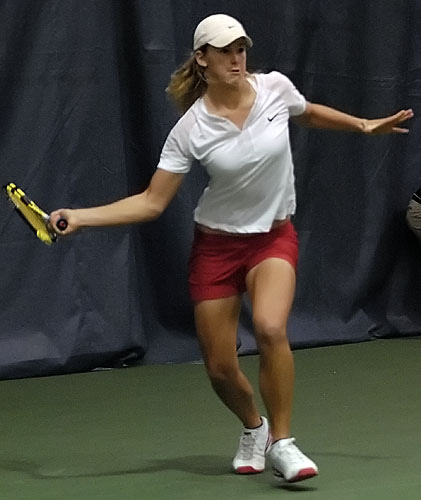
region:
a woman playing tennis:
[206, 132, 420, 450]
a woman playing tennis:
[114, 185, 311, 465]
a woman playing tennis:
[107, 68, 291, 398]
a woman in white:
[166, 122, 290, 420]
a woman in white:
[126, 190, 298, 488]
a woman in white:
[120, 3, 400, 438]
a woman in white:
[196, 128, 370, 474]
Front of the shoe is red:
[292, 461, 318, 482]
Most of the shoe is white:
[267, 433, 313, 476]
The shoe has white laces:
[233, 427, 256, 456]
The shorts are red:
[188, 228, 297, 301]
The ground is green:
[0, 399, 160, 477]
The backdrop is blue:
[20, 287, 135, 357]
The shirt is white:
[165, 82, 306, 226]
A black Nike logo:
[258, 106, 282, 132]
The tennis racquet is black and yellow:
[6, 178, 73, 245]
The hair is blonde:
[157, 56, 211, 105]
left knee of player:
[227, 286, 325, 380]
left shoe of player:
[256, 437, 317, 496]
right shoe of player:
[219, 407, 285, 484]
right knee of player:
[185, 347, 252, 401]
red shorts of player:
[182, 227, 338, 303]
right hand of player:
[38, 203, 107, 261]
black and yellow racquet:
[13, 199, 68, 255]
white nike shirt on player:
[200, 98, 362, 237]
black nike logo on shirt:
[241, 110, 288, 125]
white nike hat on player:
[184, 10, 285, 46]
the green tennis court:
[60, 379, 170, 444]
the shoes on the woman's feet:
[226, 416, 319, 483]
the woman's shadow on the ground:
[32, 438, 229, 498]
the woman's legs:
[188, 214, 320, 485]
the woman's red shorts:
[189, 214, 299, 303]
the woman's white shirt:
[153, 72, 306, 228]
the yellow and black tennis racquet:
[3, 179, 72, 247]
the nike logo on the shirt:
[261, 110, 278, 124]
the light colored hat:
[186, 10, 253, 51]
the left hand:
[363, 103, 415, 141]